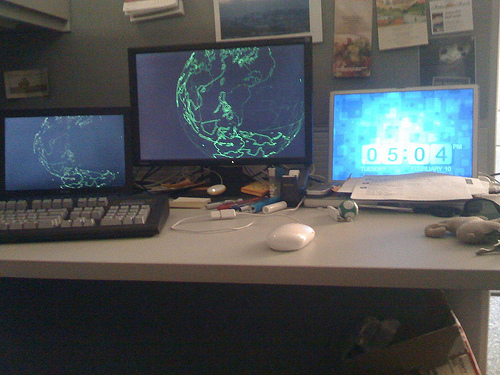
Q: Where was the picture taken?
A: An office.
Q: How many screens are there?
A: Three.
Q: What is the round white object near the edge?
A: A mouse.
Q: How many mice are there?
A: One.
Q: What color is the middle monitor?
A: Black.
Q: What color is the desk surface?
A: Gray.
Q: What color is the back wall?
A: Gray.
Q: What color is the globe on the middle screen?
A: Green.